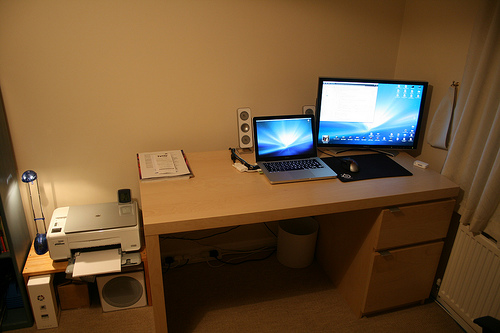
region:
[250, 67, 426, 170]
two monitors sitting on table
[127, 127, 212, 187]
papers neatly stacked in desk corner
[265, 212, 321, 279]
small wastepaper basket under the desk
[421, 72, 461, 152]
curtain tieback hanging on wall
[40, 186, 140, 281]
printer with paper on tray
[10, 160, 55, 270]
slender lamp illuminating from corner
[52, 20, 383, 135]
blank tan wall in back of desk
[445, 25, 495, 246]
curtain hanging next to desk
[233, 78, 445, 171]
blue and white pattern on monitors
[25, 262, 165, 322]
geometric office equipment on shelf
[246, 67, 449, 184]
Computers sitting on desk.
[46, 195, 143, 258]
Printer sitting on desk.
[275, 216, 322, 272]
Trash can under desk.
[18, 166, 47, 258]
Lamp sitting on desk.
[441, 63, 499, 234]
Curtains at the window.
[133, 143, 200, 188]
A book sitting on desk.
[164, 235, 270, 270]
Power cords under desk.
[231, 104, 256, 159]
Clock sitting on desk.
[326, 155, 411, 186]
Mouse pad on desk.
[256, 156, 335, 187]
Key board on desk.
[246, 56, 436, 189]
two monitors that are on next to each other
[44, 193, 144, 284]
printer with paper ready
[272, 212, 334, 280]
a white trash can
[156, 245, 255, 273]
an extended outlet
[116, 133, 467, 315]
a wood computer desk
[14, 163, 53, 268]
a modern lamp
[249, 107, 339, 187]
a laptop that is on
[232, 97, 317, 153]
two computer speakers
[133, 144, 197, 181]
a stack of papers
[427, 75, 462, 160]
the piece that holds the curtains back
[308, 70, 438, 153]
a computer monitor on a desk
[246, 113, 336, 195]
a laptop computer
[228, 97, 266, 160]
a stereo speaker for the computer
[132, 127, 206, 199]
a book sitting on a desk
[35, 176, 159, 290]
a printer for the computer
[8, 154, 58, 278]
a lamp sitting on a shelf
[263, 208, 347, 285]
a trash can under the desk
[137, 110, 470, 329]
a desk in the corner of the room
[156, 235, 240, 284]
a power strip for the computer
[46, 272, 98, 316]
a cardboard box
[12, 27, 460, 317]
A neat desk with two computers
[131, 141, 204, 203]
A stack of paper on a desk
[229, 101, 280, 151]
A speaker behind a computer screen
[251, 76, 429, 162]
Two computer with blue screens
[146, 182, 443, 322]
A desk with two drawers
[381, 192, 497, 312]
Heating element near a desk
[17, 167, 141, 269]
A printer and a small lamp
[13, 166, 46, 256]
Blue desk lamp in front of beige wall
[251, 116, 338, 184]
A laptop computer with the power on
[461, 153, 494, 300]
Beige curtain above a heating element